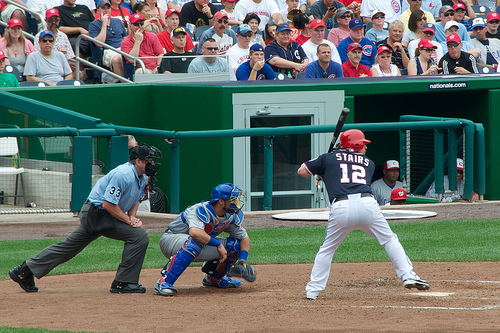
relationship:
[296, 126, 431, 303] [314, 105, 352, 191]
batter holding bat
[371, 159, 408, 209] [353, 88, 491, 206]
person sitting in dug out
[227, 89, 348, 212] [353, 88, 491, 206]
door frame inside dug out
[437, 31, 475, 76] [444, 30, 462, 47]
man wearing hat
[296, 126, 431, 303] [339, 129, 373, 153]
batter wearing helmet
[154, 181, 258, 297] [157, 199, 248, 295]
catcher wearing uniform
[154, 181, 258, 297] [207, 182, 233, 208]
catcher wearing helmet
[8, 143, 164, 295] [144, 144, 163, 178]
umpire wearing safety mask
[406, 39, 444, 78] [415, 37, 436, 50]
woman wearing hat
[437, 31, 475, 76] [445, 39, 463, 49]
man wearing sunglasses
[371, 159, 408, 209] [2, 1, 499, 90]
person sitting in stand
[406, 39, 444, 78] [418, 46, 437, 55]
woman wearing sunglasses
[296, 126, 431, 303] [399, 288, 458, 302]
batter at plate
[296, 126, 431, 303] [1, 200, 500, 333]
batter on field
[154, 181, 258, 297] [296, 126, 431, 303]
catcher behind batter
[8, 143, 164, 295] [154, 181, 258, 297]
umpire behind catcher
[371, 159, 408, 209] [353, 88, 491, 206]
person inside of dug out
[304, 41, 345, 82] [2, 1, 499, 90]
spectator sitting in stand